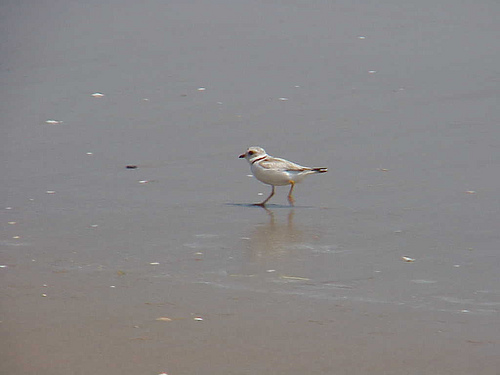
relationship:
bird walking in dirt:
[238, 146, 328, 206] [226, 195, 306, 231]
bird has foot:
[238, 146, 328, 206] [249, 199, 264, 207]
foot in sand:
[249, 199, 264, 207] [0, 27, 494, 372]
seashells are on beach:
[43, 113, 67, 129] [4, 0, 498, 372]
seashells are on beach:
[89, 85, 106, 102] [4, 0, 498, 372]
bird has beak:
[238, 146, 328, 206] [236, 152, 246, 161]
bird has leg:
[238, 146, 328, 206] [288, 180, 293, 200]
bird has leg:
[238, 146, 328, 206] [254, 186, 276, 206]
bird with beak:
[208, 127, 377, 222] [237, 151, 246, 161]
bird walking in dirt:
[208, 127, 377, 222] [6, 3, 488, 373]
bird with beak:
[238, 146, 328, 206] [225, 145, 249, 165]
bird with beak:
[238, 146, 328, 206] [226, 145, 252, 186]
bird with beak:
[238, 146, 328, 206] [238, 150, 250, 159]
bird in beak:
[238, 146, 328, 206] [235, 149, 249, 161]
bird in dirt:
[238, 146, 328, 206] [6, 3, 488, 373]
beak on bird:
[236, 154, 246, 161] [238, 146, 328, 206]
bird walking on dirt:
[238, 146, 328, 206] [6, 3, 488, 373]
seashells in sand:
[126, 292, 217, 332] [0, 27, 494, 372]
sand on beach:
[237, 226, 284, 247] [4, 0, 498, 372]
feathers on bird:
[297, 166, 328, 176] [229, 138, 316, 224]